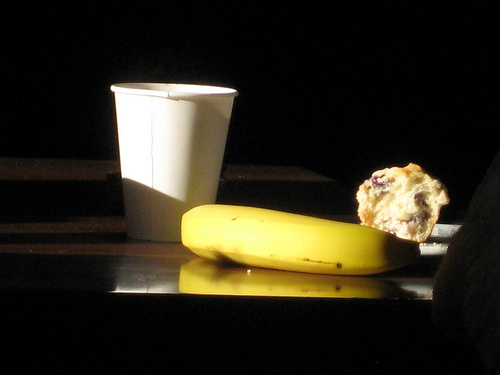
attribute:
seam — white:
[147, 90, 156, 240]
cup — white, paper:
[110, 78, 240, 242]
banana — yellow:
[168, 196, 433, 280]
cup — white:
[106, 66, 240, 244]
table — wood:
[2, 165, 482, 341]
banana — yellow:
[179, 195, 428, 284]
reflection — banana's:
[154, 253, 397, 315]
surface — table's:
[11, 202, 472, 325]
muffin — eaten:
[351, 159, 445, 249]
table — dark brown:
[8, 177, 478, 331]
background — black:
[4, 29, 495, 231]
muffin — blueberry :
[352, 151, 445, 247]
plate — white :
[430, 228, 447, 288]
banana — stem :
[410, 236, 418, 265]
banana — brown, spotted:
[152, 191, 398, 282]